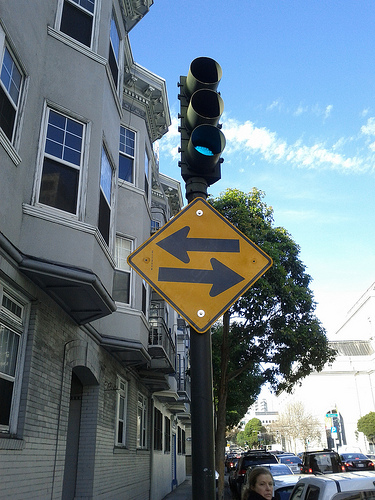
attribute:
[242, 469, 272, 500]
hair — brown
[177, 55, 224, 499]
sign post — black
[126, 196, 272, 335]
street sign — yellow, diamond-shaped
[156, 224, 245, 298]
arrows — black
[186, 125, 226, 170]
light — green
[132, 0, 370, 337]
sky — clear, blue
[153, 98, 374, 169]
clouds — wispy, white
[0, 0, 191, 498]
building — white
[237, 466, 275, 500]
woman — waiting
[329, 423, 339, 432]
parking sign — blue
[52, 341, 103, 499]
archway — white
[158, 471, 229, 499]
sidewalk — cement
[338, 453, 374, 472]
car — black, driving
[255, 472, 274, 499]
face — looking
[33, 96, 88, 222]
window — white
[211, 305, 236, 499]
tree trunk — slender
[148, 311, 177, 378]
balcony — gray